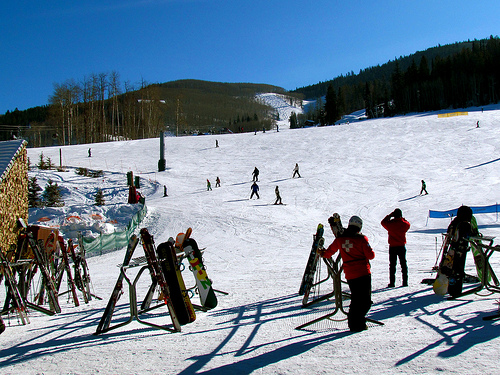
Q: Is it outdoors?
A: Yes, it is outdoors.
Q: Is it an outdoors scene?
A: Yes, it is outdoors.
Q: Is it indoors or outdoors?
A: It is outdoors.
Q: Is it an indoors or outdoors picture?
A: It is outdoors.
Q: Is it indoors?
A: No, it is outdoors.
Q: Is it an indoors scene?
A: No, it is outdoors.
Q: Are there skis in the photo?
A: Yes, there are skis.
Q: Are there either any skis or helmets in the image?
A: Yes, there are skis.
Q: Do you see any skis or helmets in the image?
A: Yes, there are skis.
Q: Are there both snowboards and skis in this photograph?
A: Yes, there are both skis and a snowboard.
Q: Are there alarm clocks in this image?
A: No, there are no alarm clocks.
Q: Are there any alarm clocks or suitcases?
A: No, there are no alarm clocks or suitcases.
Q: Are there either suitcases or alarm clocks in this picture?
A: No, there are no alarm clocks or suitcases.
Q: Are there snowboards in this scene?
A: Yes, there is a snowboard.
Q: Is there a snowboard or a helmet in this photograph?
A: Yes, there is a snowboard.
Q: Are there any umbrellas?
A: No, there are no umbrellas.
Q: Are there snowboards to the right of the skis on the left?
A: Yes, there is a snowboard to the right of the skis.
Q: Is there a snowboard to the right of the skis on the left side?
A: Yes, there is a snowboard to the right of the skis.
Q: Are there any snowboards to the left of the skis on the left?
A: No, the snowboard is to the right of the skis.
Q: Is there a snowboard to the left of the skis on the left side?
A: No, the snowboard is to the right of the skis.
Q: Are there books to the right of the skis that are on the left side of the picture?
A: No, there is a snowboard to the right of the skis.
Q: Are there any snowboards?
A: Yes, there is a snowboard.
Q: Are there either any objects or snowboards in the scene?
A: Yes, there is a snowboard.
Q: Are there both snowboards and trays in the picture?
A: No, there is a snowboard but no trays.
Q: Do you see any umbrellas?
A: No, there are no umbrellas.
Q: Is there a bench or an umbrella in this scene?
A: No, there are no umbrellas or benches.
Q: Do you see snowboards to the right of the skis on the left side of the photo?
A: Yes, there is a snowboard to the right of the skis.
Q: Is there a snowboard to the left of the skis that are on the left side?
A: No, the snowboard is to the right of the skis.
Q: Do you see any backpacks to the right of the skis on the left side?
A: No, there is a snowboard to the right of the skis.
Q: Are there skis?
A: Yes, there are skis.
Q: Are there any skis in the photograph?
A: Yes, there are skis.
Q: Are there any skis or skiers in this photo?
A: Yes, there are skis.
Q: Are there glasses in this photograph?
A: No, there are no glasses.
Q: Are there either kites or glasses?
A: No, there are no glasses or kites.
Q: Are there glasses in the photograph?
A: No, there are no glasses.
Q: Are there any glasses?
A: No, there are no glasses.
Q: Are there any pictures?
A: No, there are no pictures.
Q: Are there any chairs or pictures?
A: No, there are no pictures or chairs.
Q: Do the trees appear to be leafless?
A: Yes, the trees are leafless.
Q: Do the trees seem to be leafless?
A: Yes, the trees are leafless.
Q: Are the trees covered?
A: No, the trees are leafless.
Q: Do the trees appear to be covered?
A: No, the trees are leafless.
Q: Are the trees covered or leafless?
A: The trees are leafless.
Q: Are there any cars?
A: No, there are no cars.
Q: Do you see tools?
A: No, there are no tools.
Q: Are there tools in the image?
A: No, there are no tools.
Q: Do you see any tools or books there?
A: No, there are no tools or books.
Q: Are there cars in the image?
A: No, there are no cars.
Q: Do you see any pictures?
A: No, there are no pictures.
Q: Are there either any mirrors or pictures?
A: No, there are no pictures or mirrors.